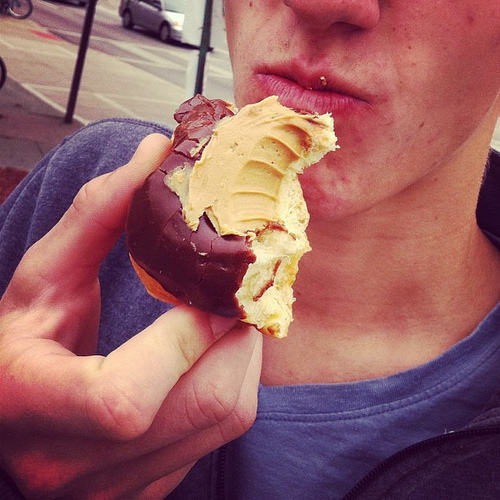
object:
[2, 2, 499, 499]
teen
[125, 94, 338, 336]
donut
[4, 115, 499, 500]
shirt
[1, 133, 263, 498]
hand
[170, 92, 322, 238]
peanut butter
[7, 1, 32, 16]
tire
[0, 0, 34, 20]
bike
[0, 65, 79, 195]
sidewalk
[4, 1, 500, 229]
city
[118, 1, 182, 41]
sedan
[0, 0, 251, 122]
street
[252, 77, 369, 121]
lips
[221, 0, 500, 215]
face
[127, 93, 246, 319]
chocolate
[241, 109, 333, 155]
bites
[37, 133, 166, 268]
thumb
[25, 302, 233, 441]
finger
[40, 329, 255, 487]
finger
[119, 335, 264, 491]
finger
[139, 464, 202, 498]
finger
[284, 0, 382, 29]
nose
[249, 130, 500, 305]
neck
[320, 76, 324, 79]
spots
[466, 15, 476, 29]
pimple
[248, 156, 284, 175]
lines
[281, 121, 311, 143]
line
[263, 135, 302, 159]
line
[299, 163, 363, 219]
chin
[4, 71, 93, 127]
lines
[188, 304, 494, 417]
seam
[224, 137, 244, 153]
blemishes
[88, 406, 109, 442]
wrinkles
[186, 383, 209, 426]
wrinkles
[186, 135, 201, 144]
cracks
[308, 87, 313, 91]
crumb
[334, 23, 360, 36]
nostril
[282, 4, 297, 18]
nostril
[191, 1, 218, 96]
pole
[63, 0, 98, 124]
pole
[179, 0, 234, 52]
signs